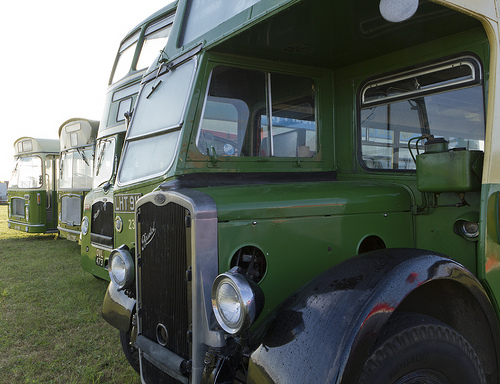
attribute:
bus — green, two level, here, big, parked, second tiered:
[102, 0, 500, 383]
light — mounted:
[215, 279, 245, 330]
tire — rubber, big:
[354, 312, 488, 383]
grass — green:
[1, 204, 141, 384]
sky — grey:
[1, 0, 175, 180]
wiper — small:
[145, 61, 166, 102]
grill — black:
[137, 201, 191, 357]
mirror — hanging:
[381, 1, 420, 23]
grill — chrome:
[60, 194, 82, 225]